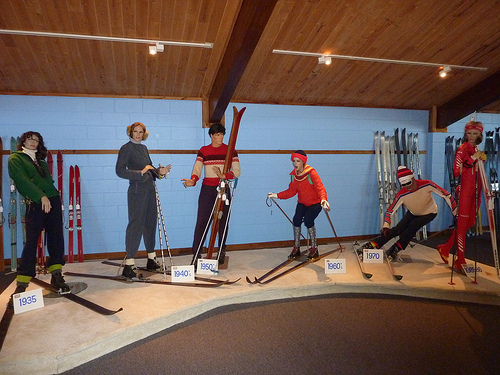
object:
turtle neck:
[20, 148, 39, 168]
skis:
[255, 245, 347, 287]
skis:
[206, 106, 246, 260]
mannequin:
[356, 166, 457, 262]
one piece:
[116, 141, 167, 184]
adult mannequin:
[115, 122, 172, 279]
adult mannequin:
[7, 131, 70, 299]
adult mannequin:
[179, 123, 240, 269]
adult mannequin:
[437, 121, 488, 275]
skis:
[0, 282, 31, 350]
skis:
[62, 270, 227, 289]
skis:
[244, 246, 312, 283]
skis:
[352, 240, 373, 279]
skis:
[477, 148, 499, 275]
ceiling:
[0, 0, 483, 113]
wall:
[223, 103, 498, 243]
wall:
[2, 95, 211, 257]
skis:
[373, 130, 382, 231]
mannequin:
[269, 150, 334, 260]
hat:
[398, 165, 416, 186]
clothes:
[115, 141, 164, 259]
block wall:
[253, 115, 356, 212]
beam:
[207, 0, 274, 124]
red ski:
[73, 167, 89, 263]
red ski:
[68, 164, 77, 262]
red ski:
[55, 151, 64, 202]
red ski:
[46, 151, 54, 179]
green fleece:
[7, 149, 58, 202]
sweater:
[189, 142, 241, 187]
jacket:
[277, 164, 327, 207]